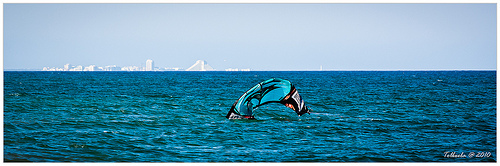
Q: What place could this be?
A: It is an ocean.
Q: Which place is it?
A: It is an ocean.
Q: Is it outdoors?
A: Yes, it is outdoors.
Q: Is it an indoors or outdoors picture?
A: It is outdoors.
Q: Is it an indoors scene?
A: No, it is outdoors.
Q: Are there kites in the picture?
A: Yes, there is a kite.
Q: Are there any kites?
A: Yes, there is a kite.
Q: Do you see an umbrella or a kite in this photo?
A: Yes, there is a kite.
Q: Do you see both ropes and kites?
A: No, there is a kite but no ropes.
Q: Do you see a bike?
A: No, there are no bikes.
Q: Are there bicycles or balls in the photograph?
A: No, there are no bicycles or balls.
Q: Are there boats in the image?
A: No, there are no boats.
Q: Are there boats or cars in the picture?
A: No, there are no boats or cars.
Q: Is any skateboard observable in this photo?
A: No, there are no skateboards.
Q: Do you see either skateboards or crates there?
A: No, there are no skateboards or crates.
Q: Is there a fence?
A: No, there are no fences.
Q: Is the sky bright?
A: Yes, the sky is bright.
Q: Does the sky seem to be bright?
A: Yes, the sky is bright.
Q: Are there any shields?
A: No, there are no shields.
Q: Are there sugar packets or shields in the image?
A: No, there are no shields or sugar packets.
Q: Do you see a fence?
A: No, there are no fences.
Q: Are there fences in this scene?
A: No, there are no fences.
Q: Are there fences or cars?
A: No, there are no fences or cars.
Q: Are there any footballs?
A: No, there are no footballs.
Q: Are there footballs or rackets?
A: No, there are no footballs or rackets.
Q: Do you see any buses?
A: No, there are no buses.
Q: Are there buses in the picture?
A: No, there are no buses.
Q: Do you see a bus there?
A: No, there are no buses.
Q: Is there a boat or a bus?
A: No, there are no buses or boats.